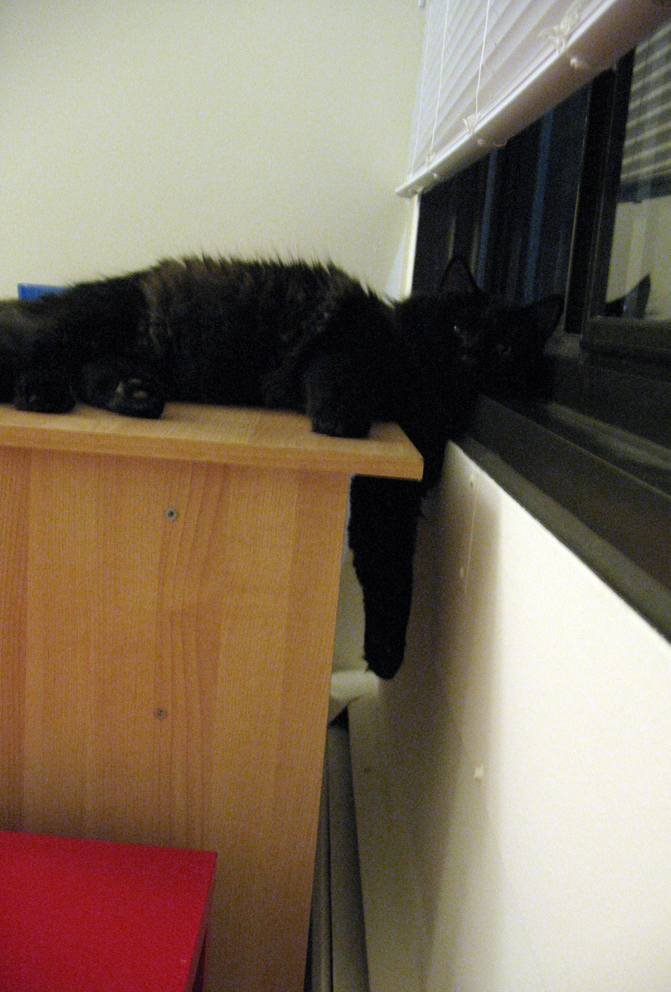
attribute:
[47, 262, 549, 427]
cat — black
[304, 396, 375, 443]
paw — on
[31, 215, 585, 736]
cat — black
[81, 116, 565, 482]
cat — black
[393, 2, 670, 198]
blinds — white